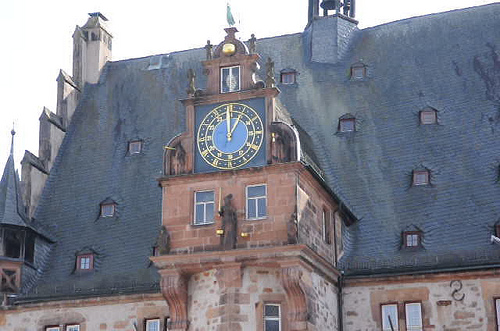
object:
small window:
[122, 134, 144, 156]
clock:
[192, 101, 263, 172]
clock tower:
[148, 32, 345, 331]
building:
[9, 7, 500, 331]